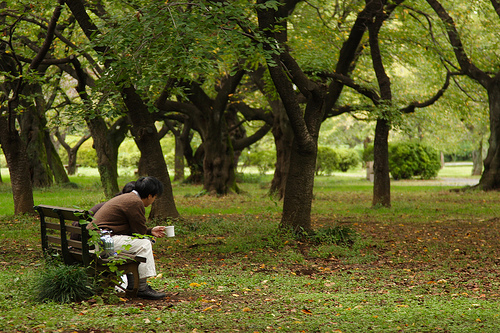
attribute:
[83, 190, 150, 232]
sweater — brown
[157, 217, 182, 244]
cup — white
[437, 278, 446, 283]
leaf — dead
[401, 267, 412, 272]
leaf — dead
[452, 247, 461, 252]
leaf — dead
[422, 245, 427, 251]
leaf — dead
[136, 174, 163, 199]
hair — black